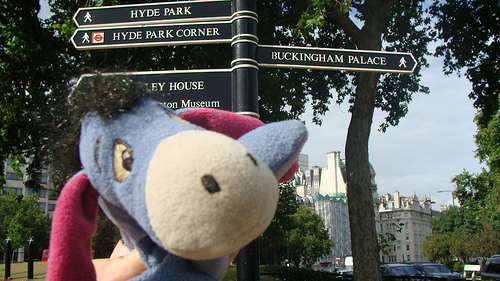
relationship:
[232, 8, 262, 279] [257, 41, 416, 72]
pole with sign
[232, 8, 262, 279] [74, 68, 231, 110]
pole with sign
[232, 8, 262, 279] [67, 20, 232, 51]
pole with sign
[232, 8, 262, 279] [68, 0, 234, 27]
pole with sign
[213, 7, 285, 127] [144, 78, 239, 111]
pole with sign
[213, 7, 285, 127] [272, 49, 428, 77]
pole with sign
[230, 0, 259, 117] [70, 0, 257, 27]
pole with sign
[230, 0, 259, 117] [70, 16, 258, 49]
pole with sign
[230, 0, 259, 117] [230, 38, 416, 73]
pole with sign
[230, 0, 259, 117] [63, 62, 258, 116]
pole with sign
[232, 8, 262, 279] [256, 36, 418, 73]
pole with street sign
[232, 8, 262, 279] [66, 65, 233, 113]
pole with street sign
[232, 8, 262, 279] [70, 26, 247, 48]
pole with street sign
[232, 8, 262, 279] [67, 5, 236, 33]
pole with street sign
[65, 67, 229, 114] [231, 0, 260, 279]
sign on a pole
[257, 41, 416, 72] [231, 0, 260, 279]
sign on a pole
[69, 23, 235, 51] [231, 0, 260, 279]
sign on a pole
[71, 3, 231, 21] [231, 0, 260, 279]
sign on a pole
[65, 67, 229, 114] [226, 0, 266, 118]
sign on a pole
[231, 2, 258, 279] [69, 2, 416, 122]
black pole on a street signs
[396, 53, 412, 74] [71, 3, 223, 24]
emblem on sign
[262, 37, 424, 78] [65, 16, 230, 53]
emblem on sign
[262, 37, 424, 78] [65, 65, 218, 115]
emblem on sign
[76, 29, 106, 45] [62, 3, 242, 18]
emblem on sign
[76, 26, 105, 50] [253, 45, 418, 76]
emblem on sign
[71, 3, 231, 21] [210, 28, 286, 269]
sign on pole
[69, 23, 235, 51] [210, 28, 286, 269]
sign on pole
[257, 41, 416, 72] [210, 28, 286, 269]
sign on pole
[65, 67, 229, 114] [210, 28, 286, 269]
sign on pole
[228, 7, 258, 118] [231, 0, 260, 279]
stripes on pole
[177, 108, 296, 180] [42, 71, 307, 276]
ears of stuff animal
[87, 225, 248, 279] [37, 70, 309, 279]
hand on eeyore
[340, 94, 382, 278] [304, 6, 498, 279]
tree trunk of tree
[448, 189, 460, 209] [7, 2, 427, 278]
streetlight behind trees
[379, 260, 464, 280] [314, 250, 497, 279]
car parked along street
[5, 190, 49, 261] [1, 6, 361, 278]
tree in park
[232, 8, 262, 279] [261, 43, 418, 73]
pole with street sign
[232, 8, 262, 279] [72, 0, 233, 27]
pole with street sign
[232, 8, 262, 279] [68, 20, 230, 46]
pole with street sign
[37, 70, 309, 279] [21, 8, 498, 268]
eeyore flying through england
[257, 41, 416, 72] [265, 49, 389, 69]
sign to "buckingham palace"